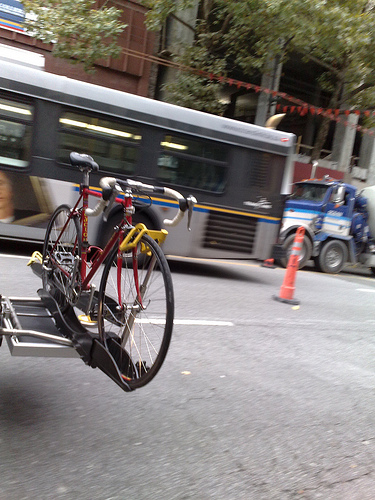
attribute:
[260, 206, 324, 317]
cone — orange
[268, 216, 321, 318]
cone — orange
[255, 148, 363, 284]
truck — blue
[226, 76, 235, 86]
flag — red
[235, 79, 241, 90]
flag — red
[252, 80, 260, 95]
flag — red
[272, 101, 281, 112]
flag — red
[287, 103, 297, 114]
flag — red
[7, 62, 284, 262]
bus — white, black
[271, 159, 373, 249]
truck — blue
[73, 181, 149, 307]
frame — red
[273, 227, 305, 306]
cone — orange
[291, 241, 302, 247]
stripe — silver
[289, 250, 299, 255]
stripe — silver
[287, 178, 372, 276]
mixer truck — blue